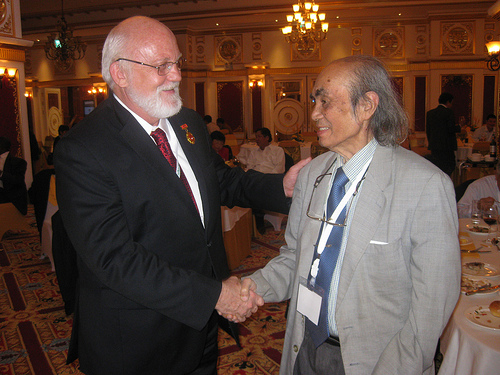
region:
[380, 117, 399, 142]
Hair falling on shoulder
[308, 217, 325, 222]
Glasses hanging on the chest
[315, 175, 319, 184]
Frames strapped on the chest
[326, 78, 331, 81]
A mark on the forehead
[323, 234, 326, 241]
Strap for the tag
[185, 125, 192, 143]
A badge on the lapel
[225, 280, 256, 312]
Hands clasped together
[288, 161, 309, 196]
Hand holding the shoulder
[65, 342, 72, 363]
Flap of jacket open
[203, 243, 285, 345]
two men are shaking hands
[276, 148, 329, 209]
the man is patting the other man on the shoulder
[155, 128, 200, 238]
the man is wearing a red neck tie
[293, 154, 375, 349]
the man is wearing a lanyard and badge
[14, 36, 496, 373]
the room appears to be a banquet hall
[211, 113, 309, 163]
people in the background are dining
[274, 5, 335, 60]
a chandelier hangs from the ceiling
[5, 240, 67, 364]
the floor is covered in designed rug/carpet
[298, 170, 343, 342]
the man is wearing a blue neck tie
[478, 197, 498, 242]
a wine glass is on the table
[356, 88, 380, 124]
ear of a person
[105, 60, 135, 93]
ear of a person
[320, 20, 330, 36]
light on a chandelier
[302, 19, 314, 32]
light on a chandelier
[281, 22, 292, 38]
light on a chandelier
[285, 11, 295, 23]
light on a chandelier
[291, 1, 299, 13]
light on a chandelier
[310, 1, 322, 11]
light on a chandelier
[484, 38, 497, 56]
light on a chandelier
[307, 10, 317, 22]
light on a chandelier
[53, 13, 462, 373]
Two men shaking hands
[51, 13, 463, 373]
Man putting his hand on another mans shoulder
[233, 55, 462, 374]
Man dressed in a gray suit and blue tie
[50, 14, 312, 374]
Man in a black suit and red tie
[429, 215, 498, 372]
Plates of food on a white tablecloth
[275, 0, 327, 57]
Lit up gold chandelier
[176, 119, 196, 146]
Red medal on a mans jacket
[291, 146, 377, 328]
White lanyard with a plastic name tag holder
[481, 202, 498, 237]
Glass of red wine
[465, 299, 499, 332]
One roll on a white plate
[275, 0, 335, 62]
hanging lights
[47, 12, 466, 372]
two men shaking hands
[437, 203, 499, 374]
table with plates of food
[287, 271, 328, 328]
a backwards name tag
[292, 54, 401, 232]
elderly man wearing glasses around neck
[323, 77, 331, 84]
a round brown mole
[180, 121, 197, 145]
a red pendant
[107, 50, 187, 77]
a pair of glasses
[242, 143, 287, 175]
a white button up shirt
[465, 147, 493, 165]
stacks of dishes